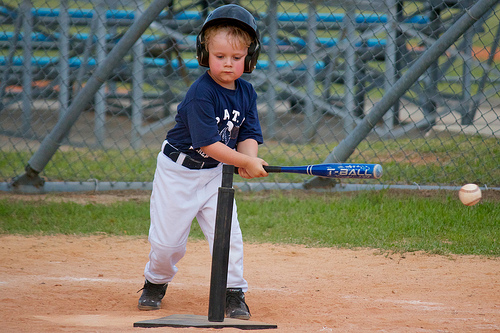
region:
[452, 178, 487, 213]
Baseball flying through the air.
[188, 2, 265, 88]
Little boy wearing a black helmet.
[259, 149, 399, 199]
Bright blue t-ball bat.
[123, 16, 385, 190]
Little boy swinging a bat.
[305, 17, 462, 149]
Chain fence behind the field.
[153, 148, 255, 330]
Stand used to hold the t-ball.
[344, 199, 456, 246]
Green grass on the field.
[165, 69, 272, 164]
Dark blue shirt with white letters.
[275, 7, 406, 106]
Rows of bleachers behind the field.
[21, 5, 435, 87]
blue bleachers behind the fence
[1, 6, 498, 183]
a chain link fence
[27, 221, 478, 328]
dirt on the baseball field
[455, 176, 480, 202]
a baseball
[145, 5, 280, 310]
a kid wearing a black helmet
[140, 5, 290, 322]
a kid wearing a blue shirt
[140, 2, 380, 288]
a kid holding a baseball bat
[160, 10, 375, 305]
a kid swinging a baseball bat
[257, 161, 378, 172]
a blue baseball bat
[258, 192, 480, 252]
grass behind the boy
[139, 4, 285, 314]
Small shild holding a baseball bat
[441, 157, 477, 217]
Red and white tball in the air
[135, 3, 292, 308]
Small child wearing a black helmet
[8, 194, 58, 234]
Small patch of green grass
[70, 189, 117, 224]
Small patch of green grass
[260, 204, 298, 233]
Small patch of green grass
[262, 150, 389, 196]
Short metal t-ball bat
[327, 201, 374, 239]
Small patch of green grass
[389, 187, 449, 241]
Small patch of green grass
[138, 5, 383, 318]
a young boy holding a bat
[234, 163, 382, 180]
a blue bat with a black handle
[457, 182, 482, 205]
a white baseball with red stripes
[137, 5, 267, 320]
a young boy wearing a batting helmet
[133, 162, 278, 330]
a black tball hitting tee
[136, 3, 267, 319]
a young boy wearing white baseball pants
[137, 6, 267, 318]
a young boy wearing a navy blue shirt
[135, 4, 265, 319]
a young boy wearing black baseball cleats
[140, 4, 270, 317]
a young boy with bright pink cheeks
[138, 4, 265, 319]
a young boy wearing a black belt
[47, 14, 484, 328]
The kid is playing baseball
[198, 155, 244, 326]
The stand on the ground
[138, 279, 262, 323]
The feet of the kid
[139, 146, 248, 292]
The kid has on white pants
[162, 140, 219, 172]
The kid is wearing a belt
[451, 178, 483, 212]
The ball is in the air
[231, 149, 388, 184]
The kid is holding a baseball bat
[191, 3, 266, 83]
The kid is wearing a baseball hat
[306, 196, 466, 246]
The grass is the color green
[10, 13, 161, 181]
The gate is made of metal